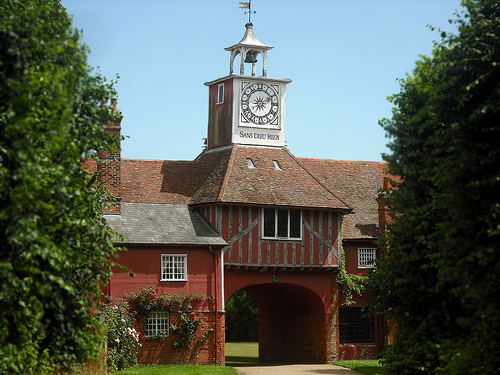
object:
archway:
[214, 266, 340, 366]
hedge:
[354, 0, 500, 375]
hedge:
[0, 0, 137, 374]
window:
[143, 310, 168, 337]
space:
[230, 307, 325, 374]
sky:
[59, 0, 473, 162]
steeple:
[205, 24, 294, 149]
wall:
[203, 289, 227, 365]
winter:
[0, 0, 500, 374]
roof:
[87, 146, 408, 209]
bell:
[244, 49, 259, 63]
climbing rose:
[106, 285, 216, 365]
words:
[239, 130, 280, 140]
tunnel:
[224, 278, 331, 368]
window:
[159, 253, 189, 282]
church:
[88, 0, 413, 372]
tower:
[184, 21, 358, 272]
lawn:
[109, 344, 434, 375]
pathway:
[226, 337, 338, 370]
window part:
[290, 207, 302, 237]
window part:
[278, 207, 288, 238]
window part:
[262, 207, 276, 237]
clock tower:
[204, 0, 293, 146]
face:
[238, 81, 281, 126]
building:
[77, 0, 403, 374]